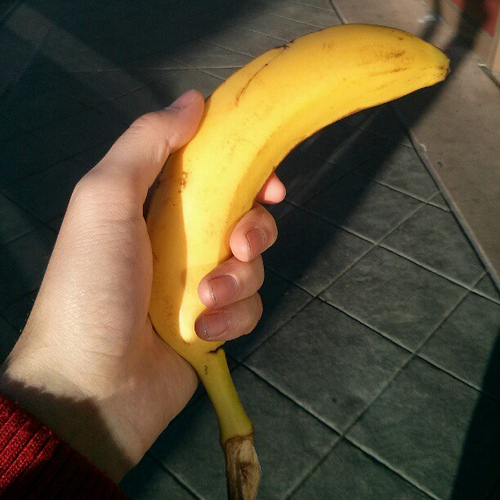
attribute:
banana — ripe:
[180, 24, 450, 222]